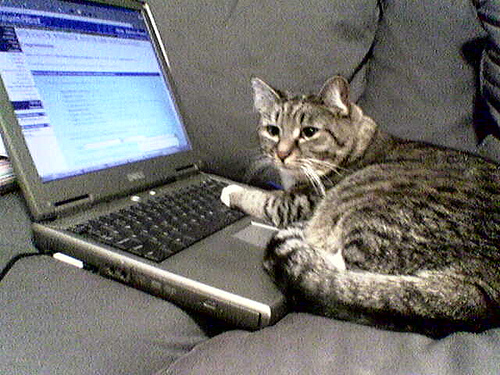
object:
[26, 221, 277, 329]
laptop side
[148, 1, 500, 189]
couch back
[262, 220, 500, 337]
tail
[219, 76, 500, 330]
cat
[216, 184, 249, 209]
paw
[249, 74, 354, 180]
head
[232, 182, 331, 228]
front leg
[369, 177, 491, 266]
cat's fur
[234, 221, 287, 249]
touchpad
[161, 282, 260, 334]
dvd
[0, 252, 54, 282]
cord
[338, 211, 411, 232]
stripe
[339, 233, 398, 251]
stripe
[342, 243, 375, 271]
stripe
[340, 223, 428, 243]
stripe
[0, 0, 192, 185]
screen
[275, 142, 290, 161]
nose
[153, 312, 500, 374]
cushion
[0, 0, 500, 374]
couch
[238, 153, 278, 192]
whiskers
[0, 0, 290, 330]
laptop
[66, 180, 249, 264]
keyboard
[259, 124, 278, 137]
eyes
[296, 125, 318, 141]
eye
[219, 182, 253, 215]
cat's paw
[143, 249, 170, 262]
keys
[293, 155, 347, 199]
whiskers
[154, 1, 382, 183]
cushion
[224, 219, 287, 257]
mouse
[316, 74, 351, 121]
ear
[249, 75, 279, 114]
ear